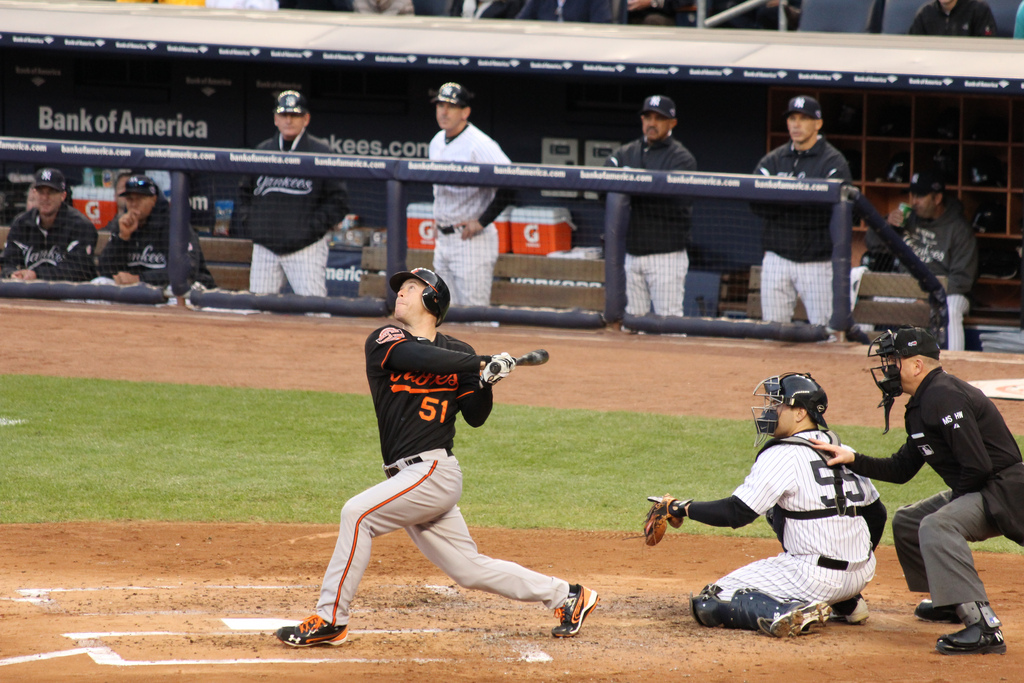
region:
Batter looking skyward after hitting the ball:
[312, 253, 601, 658]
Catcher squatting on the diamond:
[616, 361, 905, 638]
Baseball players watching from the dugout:
[31, 156, 374, 299]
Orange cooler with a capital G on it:
[511, 196, 579, 253]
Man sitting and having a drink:
[874, 162, 982, 344]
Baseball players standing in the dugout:
[246, 95, 547, 305]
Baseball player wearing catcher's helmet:
[698, 354, 858, 479]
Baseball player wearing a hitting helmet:
[319, 256, 605, 652]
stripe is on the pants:
[361, 471, 438, 536]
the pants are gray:
[337, 459, 544, 621]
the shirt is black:
[377, 317, 467, 466]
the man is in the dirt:
[718, 365, 874, 651]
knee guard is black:
[697, 585, 784, 625]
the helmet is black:
[412, 263, 450, 325]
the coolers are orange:
[397, 196, 581, 258]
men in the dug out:
[200, 108, 928, 298]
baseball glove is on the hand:
[642, 492, 682, 557]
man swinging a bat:
[279, 270, 597, 647]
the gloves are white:
[482, 355, 511, 384]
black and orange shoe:
[275, 618, 349, 644]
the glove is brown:
[646, 495, 681, 541]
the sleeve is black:
[690, 494, 754, 526]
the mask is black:
[867, 325, 903, 398]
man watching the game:
[427, 82, 517, 302]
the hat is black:
[787, 91, 820, 120]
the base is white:
[228, 618, 305, 629]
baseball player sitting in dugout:
[1, 165, 97, 283]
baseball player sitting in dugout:
[108, 171, 216, 291]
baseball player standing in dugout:
[226, 83, 357, 296]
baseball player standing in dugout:
[424, 77, 520, 306]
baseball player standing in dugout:
[604, 90, 696, 315]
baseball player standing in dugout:
[752, 92, 850, 322]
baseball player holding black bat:
[268, 266, 603, 646]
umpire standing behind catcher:
[809, 321, 1022, 654]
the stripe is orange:
[371, 472, 447, 518]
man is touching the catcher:
[766, 373, 994, 564]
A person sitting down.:
[5, 166, 100, 278]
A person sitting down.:
[95, 172, 214, 291]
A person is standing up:
[230, 84, 349, 293]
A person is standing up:
[429, 81, 513, 304]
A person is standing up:
[600, 90, 695, 318]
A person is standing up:
[749, 93, 849, 321]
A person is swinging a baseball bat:
[275, 264, 601, 650]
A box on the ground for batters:
[16, 583, 554, 663]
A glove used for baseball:
[642, 491, 684, 545]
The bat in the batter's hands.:
[483, 350, 551, 369]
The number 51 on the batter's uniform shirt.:
[418, 394, 448, 421]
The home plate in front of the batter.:
[224, 618, 314, 639]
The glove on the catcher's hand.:
[641, 499, 698, 542]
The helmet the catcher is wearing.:
[764, 372, 832, 407]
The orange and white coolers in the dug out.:
[53, 176, 579, 262]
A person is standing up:
[739, 89, 864, 321]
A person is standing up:
[574, 92, 685, 304]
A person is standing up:
[404, 92, 497, 295]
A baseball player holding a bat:
[256, 244, 620, 656]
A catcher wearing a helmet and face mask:
[737, 356, 840, 456]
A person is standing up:
[420, 92, 506, 328]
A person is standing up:
[593, 83, 710, 336]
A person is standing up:
[742, 87, 857, 366]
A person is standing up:
[875, 159, 996, 366]